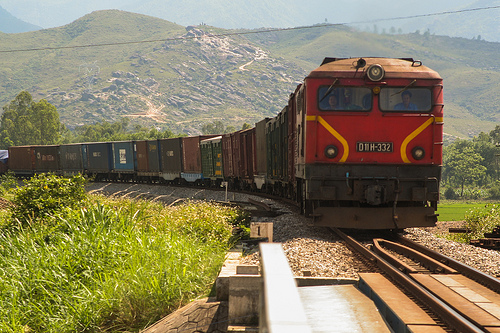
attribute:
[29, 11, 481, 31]
mountains — in background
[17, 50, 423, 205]
train — red, long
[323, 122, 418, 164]
stripe — yellow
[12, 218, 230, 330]
grass — green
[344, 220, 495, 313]
tracks — brown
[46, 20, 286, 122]
hill — rocky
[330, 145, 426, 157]
headlights — off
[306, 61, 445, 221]
engine — red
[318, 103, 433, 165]
stripes — yellow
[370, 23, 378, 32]
tree — in distance, distant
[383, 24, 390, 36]
tree — distant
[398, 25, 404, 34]
tree — in distance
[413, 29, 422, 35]
tree — in distance, distant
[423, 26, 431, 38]
tree — in distance